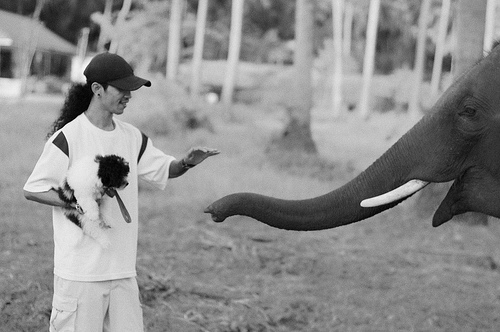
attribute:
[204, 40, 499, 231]
elephant — gray, grey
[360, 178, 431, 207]
horn — ivory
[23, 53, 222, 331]
female — petting, looking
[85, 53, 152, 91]
hat — black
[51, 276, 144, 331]
pants — white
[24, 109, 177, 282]
shirt — whtie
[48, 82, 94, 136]
hair — long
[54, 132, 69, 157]
stripe — black